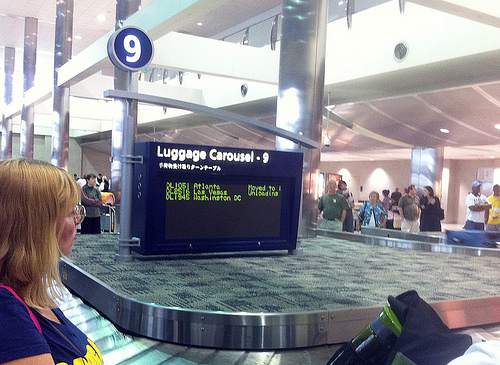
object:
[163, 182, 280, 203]
information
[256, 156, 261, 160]
dash symbol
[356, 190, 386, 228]
woman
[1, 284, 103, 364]
shirt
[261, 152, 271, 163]
number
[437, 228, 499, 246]
luggage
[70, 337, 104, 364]
lettering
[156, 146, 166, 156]
white letter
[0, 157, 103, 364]
woman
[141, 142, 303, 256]
sign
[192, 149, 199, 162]
letter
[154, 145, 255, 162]
writing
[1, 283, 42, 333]
strap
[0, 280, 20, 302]
shoulder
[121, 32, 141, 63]
nine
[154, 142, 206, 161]
word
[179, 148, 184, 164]
white letter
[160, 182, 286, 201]
lettering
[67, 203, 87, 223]
glasses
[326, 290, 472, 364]
backpack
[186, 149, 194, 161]
letter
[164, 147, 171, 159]
letter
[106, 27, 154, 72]
circle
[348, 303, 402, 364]
cup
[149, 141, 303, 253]
status board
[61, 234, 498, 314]
area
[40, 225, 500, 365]
luggage carousel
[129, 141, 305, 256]
electronic display